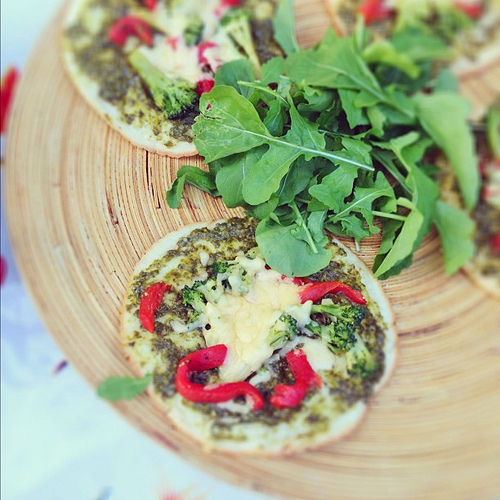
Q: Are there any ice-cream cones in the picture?
A: No, there are no ice-cream cones.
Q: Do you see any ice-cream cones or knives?
A: No, there are no ice-cream cones or knives.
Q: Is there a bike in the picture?
A: No, there are no bikes.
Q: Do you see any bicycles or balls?
A: No, there are no bicycles or balls.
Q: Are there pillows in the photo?
A: No, there are no pillows.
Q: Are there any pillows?
A: No, there are no pillows.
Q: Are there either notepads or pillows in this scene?
A: No, there are no pillows or notepads.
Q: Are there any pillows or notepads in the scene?
A: No, there are no pillows or notepads.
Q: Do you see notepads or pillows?
A: No, there are no pillows or notepads.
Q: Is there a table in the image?
A: Yes, there is a table.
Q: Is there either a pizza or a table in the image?
A: Yes, there is a table.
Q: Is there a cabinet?
A: No, there are no cabinets.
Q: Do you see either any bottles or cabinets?
A: No, there are no cabinets or bottles.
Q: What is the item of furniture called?
A: The piece of furniture is a table.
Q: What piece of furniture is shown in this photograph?
A: The piece of furniture is a table.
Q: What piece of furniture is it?
A: The piece of furniture is a table.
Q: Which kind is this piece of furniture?
A: That is a table.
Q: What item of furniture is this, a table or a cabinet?
A: That is a table.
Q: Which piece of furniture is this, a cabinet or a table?
A: That is a table.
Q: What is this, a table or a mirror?
A: This is a table.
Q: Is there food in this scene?
A: Yes, there is food.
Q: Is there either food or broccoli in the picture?
A: Yes, there is food.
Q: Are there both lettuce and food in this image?
A: Yes, there are both food and lettuce.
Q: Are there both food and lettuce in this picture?
A: Yes, there are both food and lettuce.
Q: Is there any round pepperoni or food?
A: Yes, there is round food.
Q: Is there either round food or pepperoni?
A: Yes, there is round food.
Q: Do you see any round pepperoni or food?
A: Yes, there is round food.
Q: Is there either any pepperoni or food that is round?
A: Yes, the food is round.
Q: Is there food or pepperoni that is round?
A: Yes, the food is round.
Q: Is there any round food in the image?
A: Yes, there is round food.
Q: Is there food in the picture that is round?
A: Yes, there is food that is round.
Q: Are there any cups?
A: No, there are no cups.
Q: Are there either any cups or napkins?
A: No, there are no cups or napkins.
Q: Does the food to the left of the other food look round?
A: Yes, the food is round.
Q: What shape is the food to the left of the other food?
A: The food is round.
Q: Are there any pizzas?
A: Yes, there is a pizza.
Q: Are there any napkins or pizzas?
A: Yes, there is a pizza.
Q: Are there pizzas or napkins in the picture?
A: Yes, there is a pizza.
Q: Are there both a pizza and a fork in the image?
A: No, there is a pizza but no forks.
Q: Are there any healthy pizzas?
A: Yes, there is a healthy pizza.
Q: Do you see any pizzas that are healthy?
A: Yes, there is a pizza that is healthy.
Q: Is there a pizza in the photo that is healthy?
A: Yes, there is a pizza that is healthy.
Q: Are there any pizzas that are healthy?
A: Yes, there is a pizza that is healthy.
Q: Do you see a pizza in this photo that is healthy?
A: Yes, there is a pizza that is healthy.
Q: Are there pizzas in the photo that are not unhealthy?
A: Yes, there is an healthy pizza.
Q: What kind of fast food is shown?
A: The fast food is a pizza.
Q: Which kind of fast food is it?
A: The food is a pizza.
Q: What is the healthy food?
A: The food is a pizza.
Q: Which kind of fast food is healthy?
A: The fast food is a pizza.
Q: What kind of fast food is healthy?
A: The fast food is a pizza.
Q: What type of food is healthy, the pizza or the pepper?
A: The pizza is healthy.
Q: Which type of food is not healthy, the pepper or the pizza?
A: The pepper is not healthy.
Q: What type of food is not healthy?
A: The food is a pepper.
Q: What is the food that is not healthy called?
A: The food is a pepper.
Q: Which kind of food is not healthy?
A: The food is a pepper.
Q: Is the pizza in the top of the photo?
A: Yes, the pizza is in the top of the image.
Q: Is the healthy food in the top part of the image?
A: Yes, the pizza is in the top of the image.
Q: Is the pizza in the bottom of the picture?
A: No, the pizza is in the top of the image.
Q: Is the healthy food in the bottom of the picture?
A: No, the pizza is in the top of the image.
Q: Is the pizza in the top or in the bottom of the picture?
A: The pizza is in the top of the image.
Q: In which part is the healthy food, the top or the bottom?
A: The pizza is in the top of the image.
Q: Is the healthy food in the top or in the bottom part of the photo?
A: The pizza is in the top of the image.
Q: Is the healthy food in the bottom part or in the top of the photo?
A: The pizza is in the top of the image.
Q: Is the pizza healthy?
A: Yes, the pizza is healthy.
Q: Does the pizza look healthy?
A: Yes, the pizza is healthy.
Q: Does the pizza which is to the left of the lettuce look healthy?
A: Yes, the pizza is healthy.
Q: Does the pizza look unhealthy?
A: No, the pizza is healthy.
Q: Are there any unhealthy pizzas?
A: No, there is a pizza but it is healthy.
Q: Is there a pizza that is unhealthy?
A: No, there is a pizza but it is healthy.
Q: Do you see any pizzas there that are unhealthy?
A: No, there is a pizza but it is healthy.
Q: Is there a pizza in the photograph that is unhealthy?
A: No, there is a pizza but it is healthy.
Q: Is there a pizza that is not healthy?
A: No, there is a pizza but it is healthy.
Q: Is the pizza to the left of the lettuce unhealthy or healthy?
A: The pizza is healthy.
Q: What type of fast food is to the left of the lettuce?
A: The food is a pizza.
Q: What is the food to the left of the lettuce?
A: The food is a pizza.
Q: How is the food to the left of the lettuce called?
A: The food is a pizza.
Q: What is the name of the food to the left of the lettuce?
A: The food is a pizza.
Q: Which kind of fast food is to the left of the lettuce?
A: The food is a pizza.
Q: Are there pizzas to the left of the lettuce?
A: Yes, there is a pizza to the left of the lettuce.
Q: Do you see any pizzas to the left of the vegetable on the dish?
A: Yes, there is a pizza to the left of the lettuce.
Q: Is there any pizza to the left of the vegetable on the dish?
A: Yes, there is a pizza to the left of the lettuce.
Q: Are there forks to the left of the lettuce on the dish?
A: No, there is a pizza to the left of the lettuce.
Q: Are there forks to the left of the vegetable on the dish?
A: No, there is a pizza to the left of the lettuce.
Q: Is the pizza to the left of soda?
A: No, the pizza is to the left of the lettuce.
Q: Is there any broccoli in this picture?
A: Yes, there is broccoli.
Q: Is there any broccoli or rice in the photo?
A: Yes, there is broccoli.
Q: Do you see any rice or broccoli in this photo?
A: Yes, there is broccoli.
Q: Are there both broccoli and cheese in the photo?
A: Yes, there are both broccoli and cheese.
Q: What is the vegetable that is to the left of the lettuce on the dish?
A: The vegetable is broccoli.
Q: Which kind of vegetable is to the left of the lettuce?
A: The vegetable is broccoli.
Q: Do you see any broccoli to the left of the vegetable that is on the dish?
A: Yes, there is broccoli to the left of the lettuce.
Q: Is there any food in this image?
A: Yes, there is food.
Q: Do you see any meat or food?
A: Yes, there is food.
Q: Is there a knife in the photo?
A: No, there are no knives.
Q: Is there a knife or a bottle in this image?
A: No, there are no knives or bottles.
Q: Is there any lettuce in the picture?
A: Yes, there is lettuce.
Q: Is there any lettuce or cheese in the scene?
A: Yes, there is lettuce.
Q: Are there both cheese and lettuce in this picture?
A: Yes, there are both lettuce and cheese.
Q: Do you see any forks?
A: No, there are no forks.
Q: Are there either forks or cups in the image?
A: No, there are no forks or cups.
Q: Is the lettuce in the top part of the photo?
A: Yes, the lettuce is in the top of the image.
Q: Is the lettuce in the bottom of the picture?
A: No, the lettuce is in the top of the image.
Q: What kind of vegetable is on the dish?
A: The vegetable is lettuce.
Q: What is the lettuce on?
A: The lettuce is on the dish.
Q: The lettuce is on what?
A: The lettuce is on the dish.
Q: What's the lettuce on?
A: The lettuce is on the dish.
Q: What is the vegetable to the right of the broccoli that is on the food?
A: The vegetable is lettuce.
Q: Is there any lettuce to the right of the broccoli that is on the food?
A: Yes, there is lettuce to the right of the broccoli.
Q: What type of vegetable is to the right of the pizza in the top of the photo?
A: The vegetable is lettuce.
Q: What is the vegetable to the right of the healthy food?
A: The vegetable is lettuce.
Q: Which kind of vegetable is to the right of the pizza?
A: The vegetable is lettuce.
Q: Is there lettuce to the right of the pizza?
A: Yes, there is lettuce to the right of the pizza.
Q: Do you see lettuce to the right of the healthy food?
A: Yes, there is lettuce to the right of the pizza.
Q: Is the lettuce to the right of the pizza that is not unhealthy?
A: Yes, the lettuce is to the right of the pizza.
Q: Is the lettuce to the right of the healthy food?
A: Yes, the lettuce is to the right of the pizza.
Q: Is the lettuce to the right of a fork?
A: No, the lettuce is to the right of the pizza.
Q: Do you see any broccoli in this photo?
A: Yes, there is broccoli.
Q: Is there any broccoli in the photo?
A: Yes, there is broccoli.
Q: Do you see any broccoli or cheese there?
A: Yes, there is broccoli.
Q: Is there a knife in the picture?
A: No, there are no knives.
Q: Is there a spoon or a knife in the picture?
A: No, there are no knives or spoons.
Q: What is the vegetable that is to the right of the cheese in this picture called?
A: The vegetable is broccoli.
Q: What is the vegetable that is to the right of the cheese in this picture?
A: The vegetable is broccoli.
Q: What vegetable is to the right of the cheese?
A: The vegetable is broccoli.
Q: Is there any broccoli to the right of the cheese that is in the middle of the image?
A: Yes, there is broccoli to the right of the cheese.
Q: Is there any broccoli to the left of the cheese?
A: No, the broccoli is to the right of the cheese.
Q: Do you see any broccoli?
A: Yes, there is broccoli.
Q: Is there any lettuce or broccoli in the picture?
A: Yes, there is broccoli.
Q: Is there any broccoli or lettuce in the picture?
A: Yes, there is broccoli.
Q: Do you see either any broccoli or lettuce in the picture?
A: Yes, there is broccoli.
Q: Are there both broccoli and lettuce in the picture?
A: Yes, there are both broccoli and lettuce.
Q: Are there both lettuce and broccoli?
A: Yes, there are both broccoli and lettuce.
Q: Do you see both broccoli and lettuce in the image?
A: Yes, there are both broccoli and lettuce.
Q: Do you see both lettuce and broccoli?
A: Yes, there are both broccoli and lettuce.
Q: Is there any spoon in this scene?
A: No, there are no spoons.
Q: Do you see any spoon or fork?
A: No, there are no spoons or forks.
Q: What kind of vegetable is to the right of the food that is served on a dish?
A: The vegetable is broccoli.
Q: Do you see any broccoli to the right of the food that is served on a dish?
A: Yes, there is broccoli to the right of the food.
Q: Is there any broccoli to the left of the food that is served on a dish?
A: No, the broccoli is to the right of the food.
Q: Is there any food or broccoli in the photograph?
A: Yes, there is broccoli.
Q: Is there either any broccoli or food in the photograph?
A: Yes, there is broccoli.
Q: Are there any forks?
A: No, there are no forks.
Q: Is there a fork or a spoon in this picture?
A: No, there are no forks or spoons.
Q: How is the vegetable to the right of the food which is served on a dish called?
A: The vegetable is broccoli.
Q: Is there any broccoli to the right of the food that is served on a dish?
A: Yes, there is broccoli to the right of the food.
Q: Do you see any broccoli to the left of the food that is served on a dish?
A: No, the broccoli is to the right of the food.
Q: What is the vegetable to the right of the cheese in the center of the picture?
A: The vegetable is broccoli.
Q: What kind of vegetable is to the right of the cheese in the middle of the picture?
A: The vegetable is broccoli.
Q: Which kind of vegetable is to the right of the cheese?
A: The vegetable is broccoli.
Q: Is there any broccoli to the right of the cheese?
A: Yes, there is broccoli to the right of the cheese.